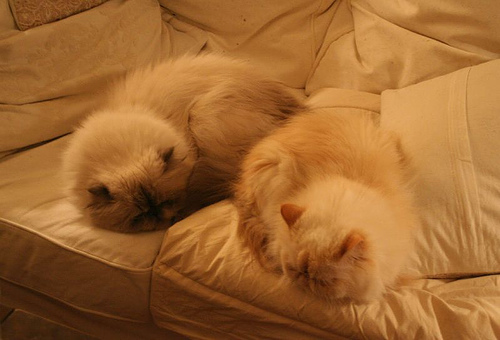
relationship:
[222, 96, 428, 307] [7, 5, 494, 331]
kitten sleeping on couch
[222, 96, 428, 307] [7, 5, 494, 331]
kitten on couch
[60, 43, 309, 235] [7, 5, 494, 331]
kitten on couch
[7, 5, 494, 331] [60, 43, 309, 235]
couch with kitten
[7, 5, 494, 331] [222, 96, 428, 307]
couch with kitten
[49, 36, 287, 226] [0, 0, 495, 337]
kitten sleeping on couch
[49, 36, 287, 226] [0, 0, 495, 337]
kitten on couch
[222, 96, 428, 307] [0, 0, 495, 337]
kitten on couch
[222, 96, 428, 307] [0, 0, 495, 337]
kitten sleeping on couch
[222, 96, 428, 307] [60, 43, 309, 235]
kitten sleeping beside kitten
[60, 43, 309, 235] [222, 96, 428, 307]
kitten sleeping beside kitten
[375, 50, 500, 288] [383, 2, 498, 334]
pillow on side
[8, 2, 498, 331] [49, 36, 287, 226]
photo of kitten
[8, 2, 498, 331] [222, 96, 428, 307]
photo of kitten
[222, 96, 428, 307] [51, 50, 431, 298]
kitten sleeping together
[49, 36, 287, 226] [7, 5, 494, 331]
kitten on couch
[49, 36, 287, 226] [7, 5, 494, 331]
kitten lying on couch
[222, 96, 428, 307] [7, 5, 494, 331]
kitten lying on couch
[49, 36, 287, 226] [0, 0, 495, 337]
kitten resting on couch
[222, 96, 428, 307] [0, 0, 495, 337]
kitten resting on couch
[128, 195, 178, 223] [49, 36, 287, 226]
eyes on kitten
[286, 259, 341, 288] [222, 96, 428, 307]
eyes on kitten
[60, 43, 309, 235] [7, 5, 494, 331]
kitten sleeping on couch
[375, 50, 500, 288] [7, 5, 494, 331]
pillow on couch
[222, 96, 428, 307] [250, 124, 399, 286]
kitten with fur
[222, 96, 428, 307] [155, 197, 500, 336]
kitten on cushion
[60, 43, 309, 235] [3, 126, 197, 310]
kitten on cushion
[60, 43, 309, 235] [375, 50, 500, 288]
kitten and pillow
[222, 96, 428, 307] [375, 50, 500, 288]
kitten and pillow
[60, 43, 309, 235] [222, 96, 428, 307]
kitten by kitten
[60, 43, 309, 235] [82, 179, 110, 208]
kitten has ear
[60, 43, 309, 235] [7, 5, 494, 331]
kitten lying on couch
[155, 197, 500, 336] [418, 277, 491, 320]
cushion with spots